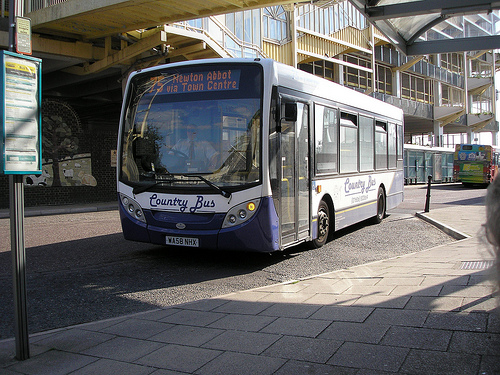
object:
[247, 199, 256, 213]
light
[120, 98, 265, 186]
windshield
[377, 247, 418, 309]
ground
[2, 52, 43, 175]
sign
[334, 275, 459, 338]
curb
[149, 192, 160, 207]
letter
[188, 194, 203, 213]
letter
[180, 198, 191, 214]
letter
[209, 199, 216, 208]
letter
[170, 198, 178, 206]
letter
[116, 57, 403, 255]
bus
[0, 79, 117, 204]
wall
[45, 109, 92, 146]
brick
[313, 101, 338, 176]
bus windows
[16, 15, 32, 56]
sticker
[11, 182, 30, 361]
pole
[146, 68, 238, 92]
destination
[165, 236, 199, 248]
plate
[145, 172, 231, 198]
windshield wiper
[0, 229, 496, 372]
shadow